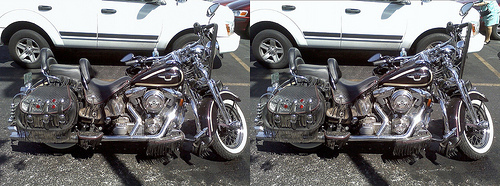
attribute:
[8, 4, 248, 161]
bike — parked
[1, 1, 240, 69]
car — white, parked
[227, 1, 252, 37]
car — red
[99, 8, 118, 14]
door handles — black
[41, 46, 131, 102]
seat — black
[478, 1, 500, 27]
dress — green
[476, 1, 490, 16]
handbag — black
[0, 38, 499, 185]
pavement — grey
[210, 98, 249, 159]
wheel — black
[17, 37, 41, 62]
rim — silver